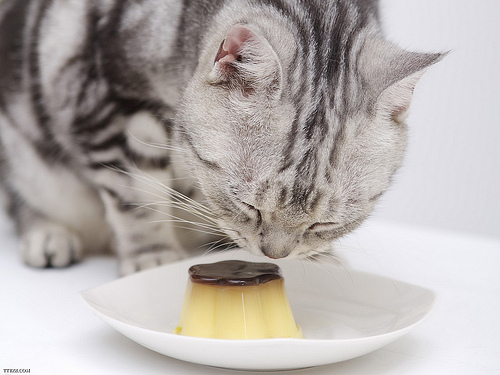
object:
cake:
[175, 259, 300, 340]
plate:
[82, 248, 436, 374]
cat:
[0, 0, 449, 278]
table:
[0, 219, 500, 375]